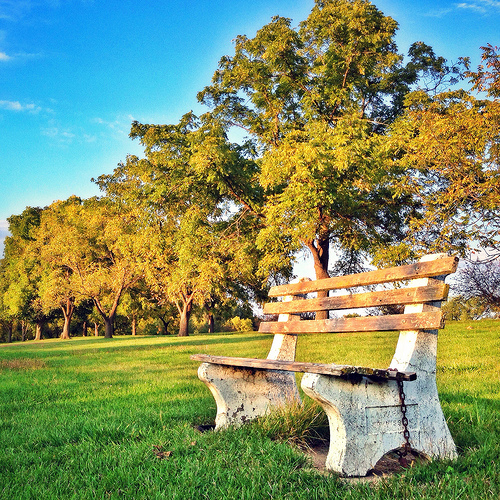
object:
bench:
[192, 253, 464, 472]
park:
[2, 3, 496, 498]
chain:
[396, 372, 413, 447]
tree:
[217, 5, 397, 327]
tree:
[397, 87, 494, 310]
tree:
[111, 115, 260, 332]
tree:
[35, 197, 91, 341]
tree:
[4, 208, 44, 339]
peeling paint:
[229, 403, 257, 427]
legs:
[303, 374, 459, 474]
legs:
[194, 364, 299, 429]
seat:
[191, 351, 416, 383]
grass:
[2, 328, 496, 499]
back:
[257, 257, 459, 333]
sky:
[0, 0, 499, 206]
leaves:
[454, 140, 482, 184]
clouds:
[2, 98, 52, 123]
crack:
[411, 362, 437, 377]